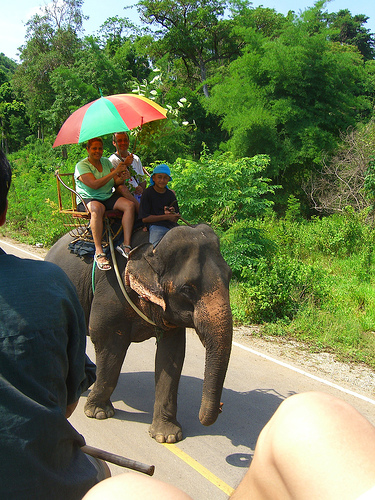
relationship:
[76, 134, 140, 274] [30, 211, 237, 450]
person riding elephant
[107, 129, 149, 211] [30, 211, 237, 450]
person riding elephant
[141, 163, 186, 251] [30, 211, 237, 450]
person riding elephant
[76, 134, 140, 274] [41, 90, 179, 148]
person under umbrella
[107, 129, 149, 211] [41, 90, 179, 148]
person under umbrella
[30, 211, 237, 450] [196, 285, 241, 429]
elephant has trunk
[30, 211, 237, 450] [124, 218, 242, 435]
elephant has head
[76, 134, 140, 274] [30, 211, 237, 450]
person sitting on elephant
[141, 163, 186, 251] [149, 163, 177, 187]
person wearing cap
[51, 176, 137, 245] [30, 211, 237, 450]
bench on elephant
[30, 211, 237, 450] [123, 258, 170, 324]
elephant has ear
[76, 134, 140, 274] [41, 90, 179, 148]
person holding umbrella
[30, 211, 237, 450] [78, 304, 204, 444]
elephant has front legs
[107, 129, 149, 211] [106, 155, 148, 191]
person wearing shirt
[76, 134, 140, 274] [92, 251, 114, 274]
person has sandal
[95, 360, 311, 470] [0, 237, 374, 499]
shadow on ground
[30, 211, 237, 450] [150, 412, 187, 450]
elephant has foot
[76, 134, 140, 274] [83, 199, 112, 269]
person has leg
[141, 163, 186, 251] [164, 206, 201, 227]
person holding stick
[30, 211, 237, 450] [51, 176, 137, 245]
elephant has bench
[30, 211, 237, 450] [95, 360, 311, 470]
elephant has shadow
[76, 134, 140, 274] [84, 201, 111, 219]
person has knee